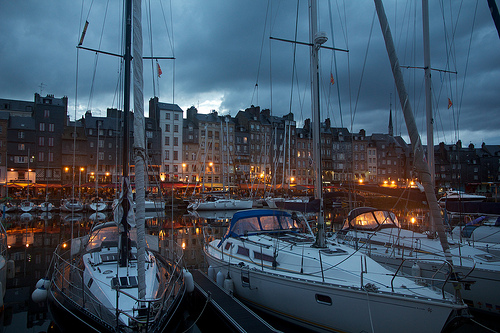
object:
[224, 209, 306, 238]
cover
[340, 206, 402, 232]
cover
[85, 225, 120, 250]
windows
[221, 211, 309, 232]
windows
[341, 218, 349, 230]
windows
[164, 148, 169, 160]
windows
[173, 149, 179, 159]
windows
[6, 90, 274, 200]
building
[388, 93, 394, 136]
tower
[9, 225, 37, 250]
water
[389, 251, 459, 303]
silver railing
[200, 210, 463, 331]
boat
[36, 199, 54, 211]
boat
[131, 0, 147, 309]
railing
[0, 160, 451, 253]
lights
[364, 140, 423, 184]
ground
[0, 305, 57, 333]
marina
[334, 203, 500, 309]
boats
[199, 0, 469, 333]
boats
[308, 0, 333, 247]
masts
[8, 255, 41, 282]
water surface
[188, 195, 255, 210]
boat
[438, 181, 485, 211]
boat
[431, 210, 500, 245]
boat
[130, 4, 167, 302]
canvas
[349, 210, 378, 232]
window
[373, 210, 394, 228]
window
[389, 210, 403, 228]
window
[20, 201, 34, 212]
boats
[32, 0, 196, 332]
boats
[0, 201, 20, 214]
sterns